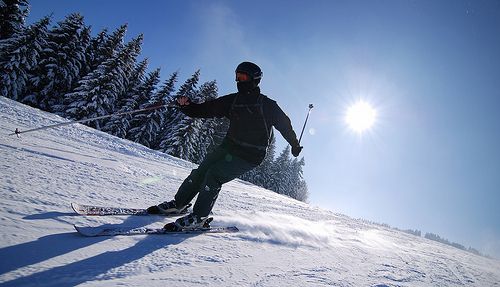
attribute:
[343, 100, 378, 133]
sun — bright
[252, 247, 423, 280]
snow — white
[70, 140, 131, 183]
snow — white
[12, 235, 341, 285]
snow — white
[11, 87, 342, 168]
poles — ski poles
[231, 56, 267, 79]
helmet — black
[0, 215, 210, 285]
shadow — Skiing man's 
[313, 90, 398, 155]
sun — bright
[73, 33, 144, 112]
trees — pine  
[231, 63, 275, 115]
helmet — black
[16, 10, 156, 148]
trees — tall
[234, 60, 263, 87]
helmet — black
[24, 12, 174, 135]
trees — green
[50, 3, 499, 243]
sky — Clear blue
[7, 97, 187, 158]
pole — Ski 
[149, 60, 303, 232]
man —  front